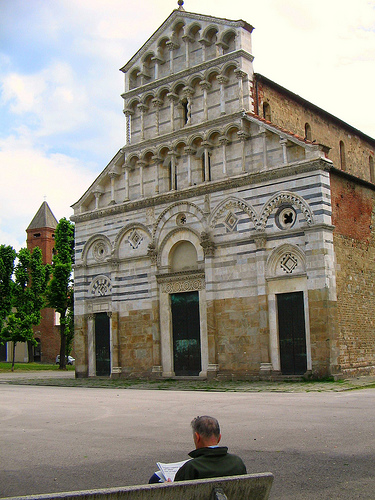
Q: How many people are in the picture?
A: One.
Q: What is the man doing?
A: Sitting on a bench and reading.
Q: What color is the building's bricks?
A: Yellow.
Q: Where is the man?
A: Bench.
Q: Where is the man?
A: On bench outside church.